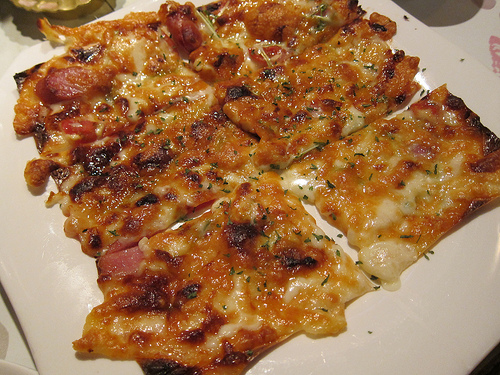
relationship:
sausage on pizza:
[35, 3, 498, 370] [6, 2, 499, 367]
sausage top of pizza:
[35, 3, 498, 370] [6, 2, 499, 367]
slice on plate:
[95, 153, 377, 366] [6, 2, 499, 367]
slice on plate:
[276, 80, 500, 296] [6, 2, 499, 367]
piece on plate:
[156, 0, 416, 166] [6, 2, 499, 367]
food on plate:
[6, 2, 499, 367] [6, 2, 499, 367]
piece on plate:
[64, 81, 262, 250] [6, 2, 499, 367]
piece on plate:
[181, 0, 367, 95] [6, 2, 499, 367]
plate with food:
[6, 2, 499, 367] [6, 2, 499, 367]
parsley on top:
[148, 53, 360, 292] [14, 0, 500, 365]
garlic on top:
[125, 6, 343, 284] [14, 0, 500, 365]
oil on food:
[82, 3, 410, 300] [6, 2, 499, 367]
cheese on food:
[31, 1, 500, 364] [6, 2, 499, 367]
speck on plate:
[360, 315, 385, 344] [6, 2, 499, 367]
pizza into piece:
[6, 2, 499, 367] [64, 81, 262, 250]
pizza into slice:
[6, 2, 499, 367] [276, 80, 500, 296]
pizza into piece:
[6, 2, 499, 367] [181, 0, 367, 95]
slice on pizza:
[78, 170, 380, 375] [6, 2, 499, 367]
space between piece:
[129, 83, 424, 246] [64, 81, 262, 250]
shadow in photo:
[409, 0, 482, 35] [8, 1, 500, 370]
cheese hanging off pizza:
[31, 1, 500, 364] [6, 2, 499, 367]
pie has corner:
[31, 1, 500, 364] [18, 11, 215, 165]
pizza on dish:
[6, 2, 499, 367] [6, 2, 499, 367]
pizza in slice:
[6, 2, 499, 367] [95, 153, 377, 366]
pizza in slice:
[6, 2, 499, 367] [276, 80, 500, 296]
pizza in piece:
[6, 2, 499, 367] [156, 0, 416, 166]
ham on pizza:
[89, 245, 153, 279] [6, 2, 499, 367]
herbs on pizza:
[223, 137, 400, 270] [6, 2, 499, 367]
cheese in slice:
[31, 1, 500, 374] [95, 153, 377, 366]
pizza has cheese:
[6, 2, 499, 367] [31, 1, 500, 364]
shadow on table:
[409, 0, 482, 35] [8, 2, 497, 371]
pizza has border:
[6, 2, 499, 367] [13, 52, 98, 186]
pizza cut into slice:
[6, 2, 499, 367] [95, 153, 377, 366]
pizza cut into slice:
[6, 2, 499, 367] [276, 80, 500, 296]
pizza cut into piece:
[6, 2, 499, 367] [156, 0, 416, 166]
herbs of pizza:
[223, 137, 400, 270] [6, 2, 499, 367]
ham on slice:
[89, 245, 153, 279] [95, 153, 377, 366]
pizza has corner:
[6, 2, 499, 367] [18, 11, 215, 165]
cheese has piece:
[31, 1, 500, 364] [70, 280, 189, 361]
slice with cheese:
[95, 153, 377, 366] [31, 1, 500, 364]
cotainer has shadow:
[9, 0, 97, 15] [8, 0, 122, 43]